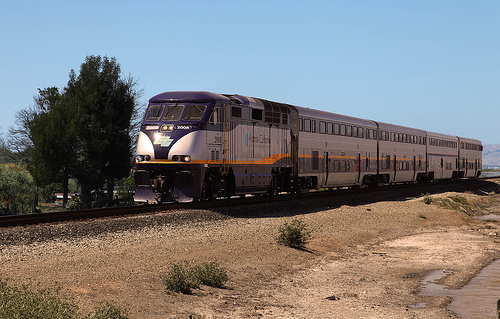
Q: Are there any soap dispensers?
A: No, there are no soap dispensers.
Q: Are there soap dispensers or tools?
A: No, there are no soap dispensers or tools.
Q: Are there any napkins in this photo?
A: No, there are no napkins.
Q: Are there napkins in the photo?
A: No, there are no napkins.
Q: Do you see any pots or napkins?
A: No, there are no napkins or pots.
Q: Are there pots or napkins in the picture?
A: No, there are no napkins or pots.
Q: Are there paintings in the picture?
A: No, there are no paintings.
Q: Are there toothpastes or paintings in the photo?
A: No, there are no paintings or toothpastes.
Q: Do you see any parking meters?
A: No, there are no parking meters.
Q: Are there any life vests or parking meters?
A: No, there are no parking meters or life vests.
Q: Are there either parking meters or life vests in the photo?
A: No, there are no parking meters or life vests.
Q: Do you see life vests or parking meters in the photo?
A: No, there are no parking meters or life vests.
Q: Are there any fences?
A: No, there are no fences.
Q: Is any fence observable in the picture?
A: No, there are no fences.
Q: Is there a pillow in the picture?
A: No, there are no pillows.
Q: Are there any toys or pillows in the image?
A: No, there are no pillows or toys.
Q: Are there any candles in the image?
A: No, there are no candles.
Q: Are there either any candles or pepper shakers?
A: No, there are no candles or pepper shakers.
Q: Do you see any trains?
A: Yes, there is a train.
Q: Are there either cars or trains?
A: Yes, there is a train.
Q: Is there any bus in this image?
A: No, there are no buses.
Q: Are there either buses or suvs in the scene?
A: No, there are no buses or suvs.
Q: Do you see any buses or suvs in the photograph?
A: No, there are no buses or suvs.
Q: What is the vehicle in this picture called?
A: The vehicle is a train.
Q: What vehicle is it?
A: The vehicle is a train.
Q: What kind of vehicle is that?
A: That is a train.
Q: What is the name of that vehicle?
A: That is a train.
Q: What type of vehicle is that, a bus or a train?
A: That is a train.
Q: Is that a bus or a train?
A: That is a train.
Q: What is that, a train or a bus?
A: That is a train.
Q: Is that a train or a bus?
A: That is a train.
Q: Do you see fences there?
A: No, there are no fences.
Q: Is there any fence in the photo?
A: No, there are no fences.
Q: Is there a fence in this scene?
A: No, there are no fences.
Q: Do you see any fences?
A: No, there are no fences.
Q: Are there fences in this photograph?
A: No, there are no fences.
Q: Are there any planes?
A: No, there are no planes.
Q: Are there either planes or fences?
A: No, there are no planes or fences.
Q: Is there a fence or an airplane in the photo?
A: No, there are no airplanes or fences.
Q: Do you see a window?
A: Yes, there is a window.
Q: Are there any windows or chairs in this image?
A: Yes, there is a window.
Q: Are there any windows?
A: Yes, there is a window.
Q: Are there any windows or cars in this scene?
A: Yes, there is a window.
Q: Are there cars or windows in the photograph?
A: Yes, there is a window.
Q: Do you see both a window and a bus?
A: No, there is a window but no buses.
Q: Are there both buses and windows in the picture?
A: No, there is a window but no buses.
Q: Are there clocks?
A: No, there are no clocks.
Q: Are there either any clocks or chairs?
A: No, there are no clocks or chairs.